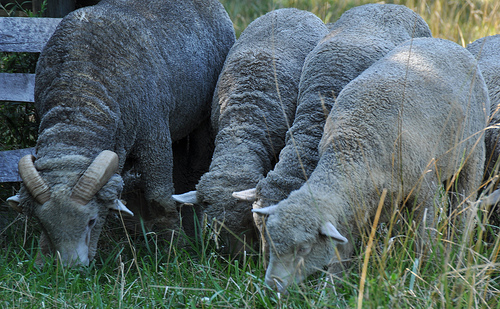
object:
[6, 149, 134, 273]
head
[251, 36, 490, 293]
sheep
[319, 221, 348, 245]
ear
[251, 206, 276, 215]
ear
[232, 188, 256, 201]
ear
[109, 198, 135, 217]
ear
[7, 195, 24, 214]
ear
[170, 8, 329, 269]
sheep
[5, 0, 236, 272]
ram head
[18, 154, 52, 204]
horn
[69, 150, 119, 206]
horn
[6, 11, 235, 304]
ram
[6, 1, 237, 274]
goat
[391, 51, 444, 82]
sun reflection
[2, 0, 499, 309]
grass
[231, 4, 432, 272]
sheep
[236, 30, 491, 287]
tea kettle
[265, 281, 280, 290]
nose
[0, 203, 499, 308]
some grass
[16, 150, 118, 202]
antlers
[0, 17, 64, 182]
fence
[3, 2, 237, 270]
ram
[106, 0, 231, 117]
wool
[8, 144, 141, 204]
ram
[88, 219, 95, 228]
eye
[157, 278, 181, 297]
part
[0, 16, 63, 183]
three boards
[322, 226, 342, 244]
edge